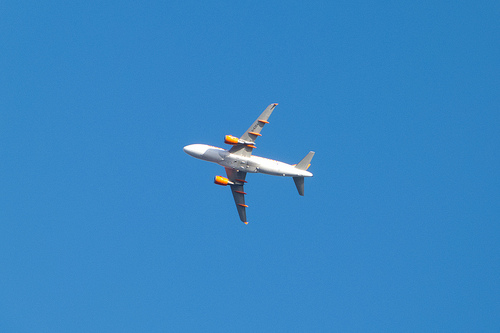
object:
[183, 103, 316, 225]
airplane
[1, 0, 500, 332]
sky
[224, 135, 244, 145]
engine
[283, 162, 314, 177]
tail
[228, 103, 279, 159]
wing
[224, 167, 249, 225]
wing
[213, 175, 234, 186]
engine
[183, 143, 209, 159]
front end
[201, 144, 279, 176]
fuselage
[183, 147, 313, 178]
bottom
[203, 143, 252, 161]
shadow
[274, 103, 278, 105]
accent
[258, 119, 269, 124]
accent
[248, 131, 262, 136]
accent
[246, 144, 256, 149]
accent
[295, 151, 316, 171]
side wing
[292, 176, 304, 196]
side wing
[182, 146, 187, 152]
tip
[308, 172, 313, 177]
tip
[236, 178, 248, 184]
accent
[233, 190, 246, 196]
accent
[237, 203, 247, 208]
accent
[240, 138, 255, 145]
mount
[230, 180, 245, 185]
mount